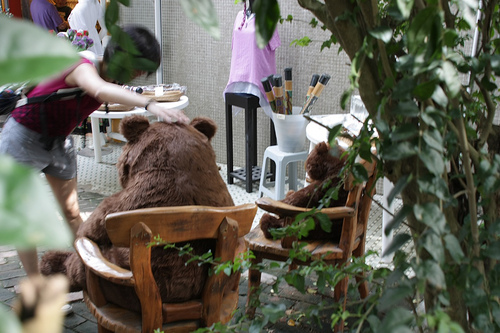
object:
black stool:
[224, 87, 276, 194]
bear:
[34, 111, 246, 328]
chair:
[72, 200, 262, 332]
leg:
[332, 263, 350, 327]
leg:
[353, 256, 372, 297]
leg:
[244, 252, 264, 312]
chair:
[241, 148, 385, 332]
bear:
[260, 141, 361, 242]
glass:
[346, 94, 372, 126]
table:
[303, 113, 395, 256]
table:
[89, 86, 190, 166]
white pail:
[267, 105, 313, 153]